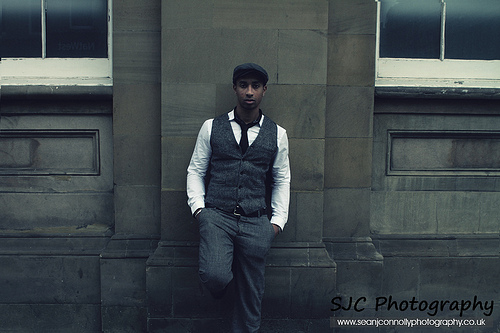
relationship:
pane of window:
[44, 2, 110, 57] [3, 0, 119, 89]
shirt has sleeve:
[183, 105, 296, 234] [184, 116, 213, 214]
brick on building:
[276, 27, 331, 84] [3, 2, 498, 332]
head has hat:
[229, 55, 267, 112] [228, 59, 269, 81]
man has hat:
[180, 61, 295, 331] [228, 59, 269, 81]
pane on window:
[376, 9, 451, 85] [375, 0, 499, 88]